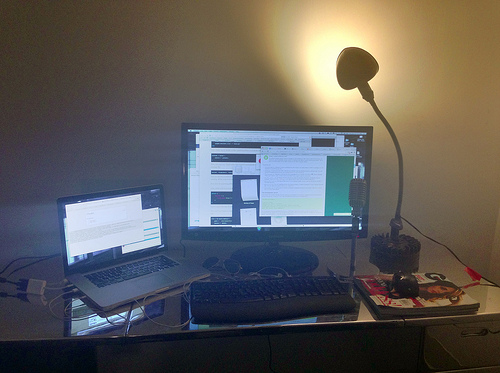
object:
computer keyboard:
[191, 276, 356, 321]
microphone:
[349, 178, 368, 207]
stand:
[349, 211, 360, 278]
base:
[327, 259, 379, 277]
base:
[231, 245, 320, 274]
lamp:
[337, 46, 420, 257]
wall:
[0, 0, 499, 240]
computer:
[56, 183, 211, 311]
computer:
[181, 121, 373, 275]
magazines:
[352, 272, 479, 316]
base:
[372, 234, 422, 255]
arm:
[369, 102, 404, 219]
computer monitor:
[179, 122, 373, 241]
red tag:
[465, 266, 482, 281]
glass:
[0, 253, 497, 336]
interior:
[2, 0, 500, 373]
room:
[1, 0, 500, 373]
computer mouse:
[392, 272, 419, 297]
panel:
[63, 188, 165, 271]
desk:
[0, 240, 498, 342]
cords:
[0, 277, 104, 321]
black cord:
[397, 217, 499, 286]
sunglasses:
[203, 256, 241, 274]